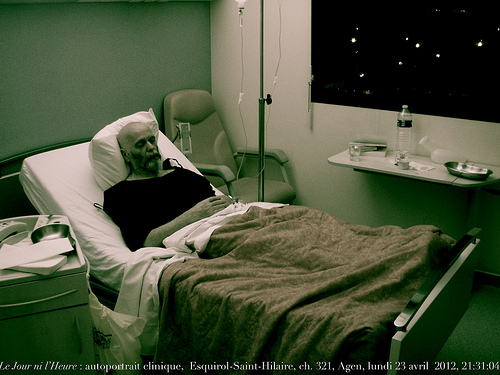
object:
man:
[99, 120, 237, 253]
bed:
[16, 125, 484, 374]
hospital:
[0, 0, 498, 375]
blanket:
[110, 200, 458, 374]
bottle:
[393, 103, 414, 154]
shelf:
[324, 140, 498, 190]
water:
[395, 152, 412, 171]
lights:
[343, 24, 372, 99]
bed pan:
[29, 222, 78, 257]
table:
[0, 211, 102, 374]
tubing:
[235, 1, 251, 202]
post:
[256, 0, 265, 202]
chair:
[160, 86, 299, 205]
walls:
[0, 0, 499, 287]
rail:
[390, 226, 485, 332]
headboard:
[0, 136, 103, 222]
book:
[0, 241, 68, 277]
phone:
[0, 218, 33, 251]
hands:
[188, 193, 236, 221]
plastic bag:
[83, 274, 148, 374]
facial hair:
[126, 151, 163, 178]